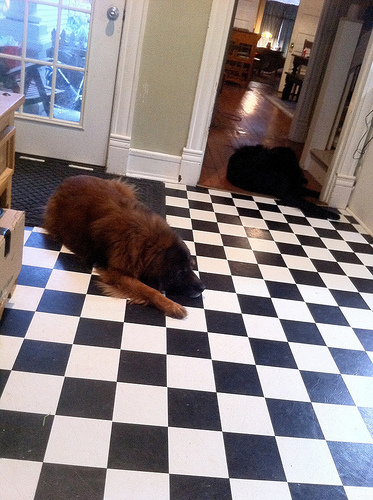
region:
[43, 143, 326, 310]
two dogs lying on floor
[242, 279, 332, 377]
black and white checkered floor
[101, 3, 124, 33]
silver knob on white door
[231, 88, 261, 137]
light reflection on wood floor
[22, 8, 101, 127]
window panes on door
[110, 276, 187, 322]
paw of reclined dog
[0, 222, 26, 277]
black tape on box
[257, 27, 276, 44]
glowing light in distant room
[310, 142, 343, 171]
bottom step on stairwell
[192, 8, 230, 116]
white trim on wall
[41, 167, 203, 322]
a large brown dog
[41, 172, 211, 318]
a large dog laying on floor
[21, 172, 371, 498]
a black and white checkered floor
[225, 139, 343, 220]
a large black dog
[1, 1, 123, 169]
a white framed door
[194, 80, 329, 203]
a brown hardwood floor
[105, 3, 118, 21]
a silver door knob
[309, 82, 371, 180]
a white stair case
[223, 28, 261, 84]
a brown wood chair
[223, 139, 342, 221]
a dog sleeping on floor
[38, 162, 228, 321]
beautiful adult brown dog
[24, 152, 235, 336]
beautiful dog with a black face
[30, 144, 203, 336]
beautiful dog with big brown eye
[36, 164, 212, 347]
big brown dog with soft fur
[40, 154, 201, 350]
big brown dog lying on the floor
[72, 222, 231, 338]
big brown dog with a black moist nose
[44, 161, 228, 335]
big dog sleeping on the floor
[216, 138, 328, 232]
black dog lying on the floor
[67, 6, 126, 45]
silver door knob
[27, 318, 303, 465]
black and white floor tiles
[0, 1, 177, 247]
Mat in front of door.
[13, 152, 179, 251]
The doormat is black.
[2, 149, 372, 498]
The floor is checkered.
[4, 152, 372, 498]
Floor is black and white.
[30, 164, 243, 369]
Dog is lying on floor.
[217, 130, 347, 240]
Dog is lying on floor.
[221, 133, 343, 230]
The dog is black.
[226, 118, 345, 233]
The dog is furry.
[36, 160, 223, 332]
The dog is brown.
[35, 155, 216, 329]
The dog is furry.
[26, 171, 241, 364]
a brown dog lying on the floor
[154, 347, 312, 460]
a black and white tile floor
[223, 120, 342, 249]
a black dog lying on the floor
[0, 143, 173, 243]
a gray rug in front of the door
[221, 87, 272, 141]
brown hard wood floors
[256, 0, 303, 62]
white curtains covering the wondow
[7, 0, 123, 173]
a white door with glass panes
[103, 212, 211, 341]
a brown dog with a black face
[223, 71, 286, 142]
light shining on the floor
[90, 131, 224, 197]
White molding on teh bottom of the walls